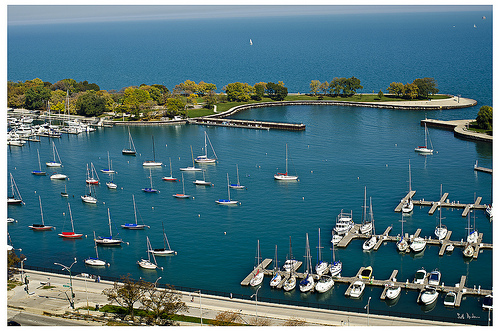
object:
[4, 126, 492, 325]
water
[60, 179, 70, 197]
yachts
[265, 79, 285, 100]
trees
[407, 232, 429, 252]
boat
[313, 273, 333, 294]
boat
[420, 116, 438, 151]
mast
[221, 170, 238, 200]
mast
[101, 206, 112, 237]
mast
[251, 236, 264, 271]
mast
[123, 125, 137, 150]
mast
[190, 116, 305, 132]
pier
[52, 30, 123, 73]
sky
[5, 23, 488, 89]
water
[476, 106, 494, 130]
trees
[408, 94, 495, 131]
water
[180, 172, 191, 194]
mast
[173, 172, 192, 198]
boat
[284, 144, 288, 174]
mast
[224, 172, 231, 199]
mast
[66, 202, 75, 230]
mast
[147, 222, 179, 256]
boat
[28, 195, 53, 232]
boat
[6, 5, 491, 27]
blue sky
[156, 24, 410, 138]
clouds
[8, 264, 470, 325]
road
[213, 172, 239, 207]
boat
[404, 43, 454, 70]
clouds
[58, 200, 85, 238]
boat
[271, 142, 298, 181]
boat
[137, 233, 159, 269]
boat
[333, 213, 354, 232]
boat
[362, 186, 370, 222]
mast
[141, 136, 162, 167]
boat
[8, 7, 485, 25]
cloud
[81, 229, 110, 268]
boat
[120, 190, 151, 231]
boat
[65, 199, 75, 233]
mast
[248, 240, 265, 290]
boat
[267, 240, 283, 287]
boat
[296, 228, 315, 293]
boat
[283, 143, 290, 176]
mast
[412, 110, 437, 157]
boat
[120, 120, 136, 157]
boat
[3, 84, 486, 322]
harbor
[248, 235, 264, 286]
boat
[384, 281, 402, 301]
boat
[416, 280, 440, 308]
boat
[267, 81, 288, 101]
tree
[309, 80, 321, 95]
tree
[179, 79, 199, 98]
tree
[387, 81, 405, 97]
tree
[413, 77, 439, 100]
tree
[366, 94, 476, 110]
beach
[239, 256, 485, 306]
dock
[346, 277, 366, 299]
boat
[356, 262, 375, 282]
boat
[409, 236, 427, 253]
boat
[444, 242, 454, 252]
boat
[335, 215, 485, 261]
dock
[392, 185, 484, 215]
dock